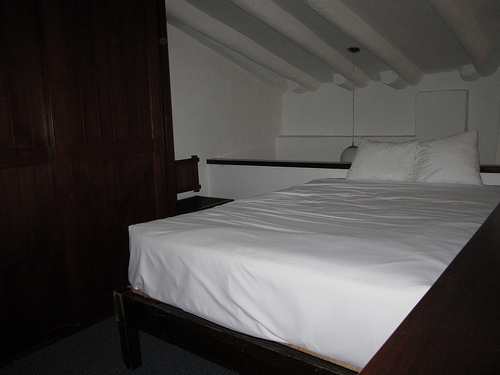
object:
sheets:
[129, 179, 500, 370]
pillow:
[346, 138, 422, 181]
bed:
[113, 128, 499, 370]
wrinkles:
[220, 202, 342, 228]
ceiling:
[164, 2, 498, 85]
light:
[168, 0, 322, 94]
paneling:
[0, 0, 177, 373]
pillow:
[415, 129, 482, 186]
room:
[3, 4, 494, 374]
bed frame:
[114, 284, 357, 375]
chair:
[171, 154, 234, 213]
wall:
[283, 73, 500, 165]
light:
[230, 0, 371, 90]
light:
[340, 145, 358, 162]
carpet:
[5, 320, 234, 372]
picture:
[416, 90, 467, 142]